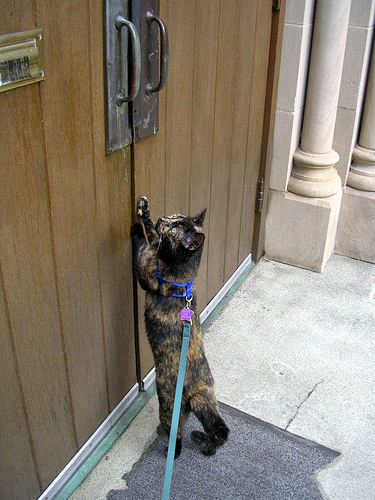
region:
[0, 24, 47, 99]
a mail slot on a door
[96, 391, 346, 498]
a worn and ripped door mat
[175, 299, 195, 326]
a purple star tag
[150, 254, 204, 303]
a blue cat harness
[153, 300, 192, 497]
a blue leash attached to a cat's harness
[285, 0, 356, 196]
a concrete pillar next to a door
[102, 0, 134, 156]
a metal handle on a door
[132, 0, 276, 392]
a brown wood door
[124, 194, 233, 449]
a black and brown cat climbing up a door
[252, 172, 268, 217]
a hinge on a door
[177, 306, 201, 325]
star shaped pet tags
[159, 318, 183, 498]
purple cat leash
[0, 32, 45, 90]
golden slot for mail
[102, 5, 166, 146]
old rust door handles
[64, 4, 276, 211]
brown wooden door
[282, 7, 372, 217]
smooth columns running along the walls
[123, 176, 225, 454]
cat with paws on the door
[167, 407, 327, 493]
torn up rug on door step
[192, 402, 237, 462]
cat's black tail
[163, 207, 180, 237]
cat with yellow beady eyes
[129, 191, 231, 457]
Cat scratching on a door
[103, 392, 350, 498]
Torn gray outdoor rug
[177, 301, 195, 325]
Fuchsia star pet ID tag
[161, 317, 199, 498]
Outstretched light blue leash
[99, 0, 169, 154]
Two metal door handles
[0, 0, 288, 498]
Large brown wood door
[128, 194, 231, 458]
Calico cat standing on hind legs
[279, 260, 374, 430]
Small crack in the concrete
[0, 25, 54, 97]
Worn golden door lock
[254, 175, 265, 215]
Bronze door hinge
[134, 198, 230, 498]
A cat on a blue leash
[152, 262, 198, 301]
A cat's blue harness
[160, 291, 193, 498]
A blue canvas leash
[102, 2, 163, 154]
A set of brass door handles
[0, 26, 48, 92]
A brass metal mail slot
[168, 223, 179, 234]
A cat's left eye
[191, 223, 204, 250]
A cat's left ear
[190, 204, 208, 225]
A cat's right ear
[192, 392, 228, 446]
A cat's tail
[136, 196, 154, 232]
A cat's right paw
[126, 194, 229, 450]
speckled cat pawing at door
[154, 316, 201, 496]
green leash of cat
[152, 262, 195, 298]
blue harness on cat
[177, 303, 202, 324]
purple id tag of cat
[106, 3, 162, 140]
two handles on door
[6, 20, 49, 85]
golden lock on door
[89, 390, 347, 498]
dark spot on cement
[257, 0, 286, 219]
hinges on the door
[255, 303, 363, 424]
crack in the pavement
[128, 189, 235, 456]
cat with green eyes